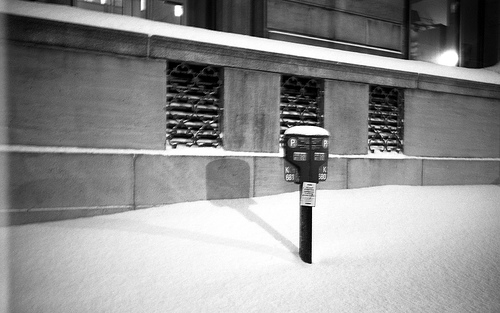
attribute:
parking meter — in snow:
[283, 125, 326, 233]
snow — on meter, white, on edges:
[281, 123, 332, 135]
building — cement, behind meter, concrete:
[45, 8, 499, 160]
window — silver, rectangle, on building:
[407, 9, 475, 80]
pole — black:
[298, 189, 317, 257]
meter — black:
[292, 166, 324, 256]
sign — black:
[134, 6, 271, 34]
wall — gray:
[13, 49, 151, 150]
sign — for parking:
[277, 126, 341, 189]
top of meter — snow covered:
[271, 114, 336, 140]